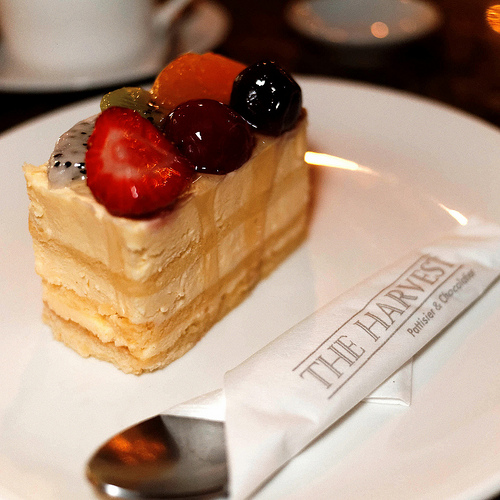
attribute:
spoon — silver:
[85, 244, 482, 499]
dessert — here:
[13, 373, 499, 492]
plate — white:
[8, 82, 496, 490]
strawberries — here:
[46, 115, 194, 212]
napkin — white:
[236, 287, 446, 479]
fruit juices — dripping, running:
[206, 184, 220, 325]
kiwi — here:
[97, 80, 170, 117]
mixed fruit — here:
[43, 49, 308, 218]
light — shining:
[308, 147, 375, 179]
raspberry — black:
[48, 114, 103, 186]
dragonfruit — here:
[147, 42, 253, 111]